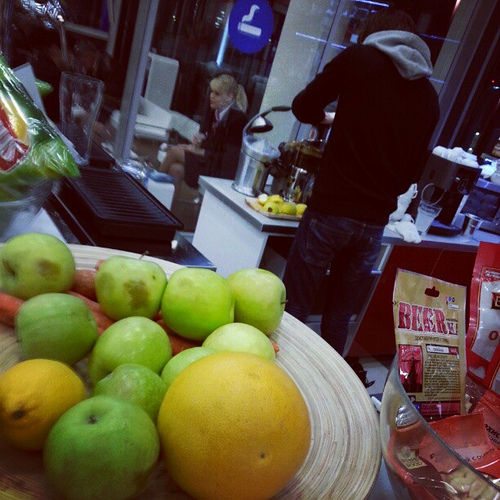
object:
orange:
[155, 350, 312, 499]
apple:
[40, 394, 160, 499]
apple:
[94, 360, 166, 422]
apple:
[88, 315, 173, 383]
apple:
[159, 266, 235, 341]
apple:
[95, 255, 167, 322]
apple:
[11, 291, 100, 368]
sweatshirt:
[289, 29, 442, 228]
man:
[281, 6, 441, 358]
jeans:
[280, 209, 385, 357]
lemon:
[0, 356, 87, 452]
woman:
[159, 72, 248, 198]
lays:
[0, 51, 80, 231]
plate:
[0, 241, 382, 499]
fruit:
[198, 318, 280, 358]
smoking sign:
[225, 3, 277, 55]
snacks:
[389, 268, 471, 434]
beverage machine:
[412, 144, 483, 236]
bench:
[112, 97, 177, 143]